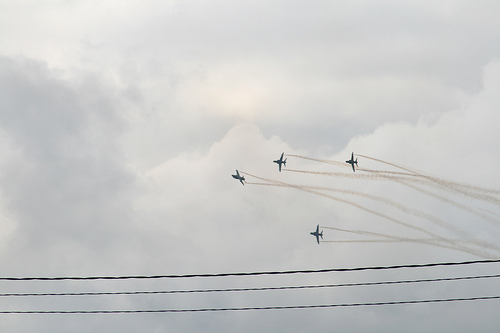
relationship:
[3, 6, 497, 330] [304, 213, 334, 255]
sky above plane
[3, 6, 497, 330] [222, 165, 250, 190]
sky above plane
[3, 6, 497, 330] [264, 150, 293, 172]
sky above plane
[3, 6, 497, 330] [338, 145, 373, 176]
sky above plane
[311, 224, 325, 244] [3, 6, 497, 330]
fighter on sky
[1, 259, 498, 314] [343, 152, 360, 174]
electrical wires beneath jet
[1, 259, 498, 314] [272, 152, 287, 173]
electrical wires beneath jet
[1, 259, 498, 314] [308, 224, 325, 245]
electrical wires beneath jet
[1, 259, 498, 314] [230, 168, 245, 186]
electrical wires beneath jet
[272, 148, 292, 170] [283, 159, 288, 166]
airplane has tail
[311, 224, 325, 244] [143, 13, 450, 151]
fighter are flying on sky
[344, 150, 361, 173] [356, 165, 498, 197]
plane leaving behind smoke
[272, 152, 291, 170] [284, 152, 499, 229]
airplane leaving behind smoke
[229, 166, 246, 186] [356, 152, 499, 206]
plane leaving behind smoke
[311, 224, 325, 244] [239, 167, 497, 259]
fighter leaving behind smoke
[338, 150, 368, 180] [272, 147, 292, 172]
plane flying with plane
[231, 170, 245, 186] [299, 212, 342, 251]
plane flying with plane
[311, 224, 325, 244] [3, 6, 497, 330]
fighter jets in sky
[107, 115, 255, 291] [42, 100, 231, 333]
fighter jets in sky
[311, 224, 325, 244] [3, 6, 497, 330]
fighter in sky